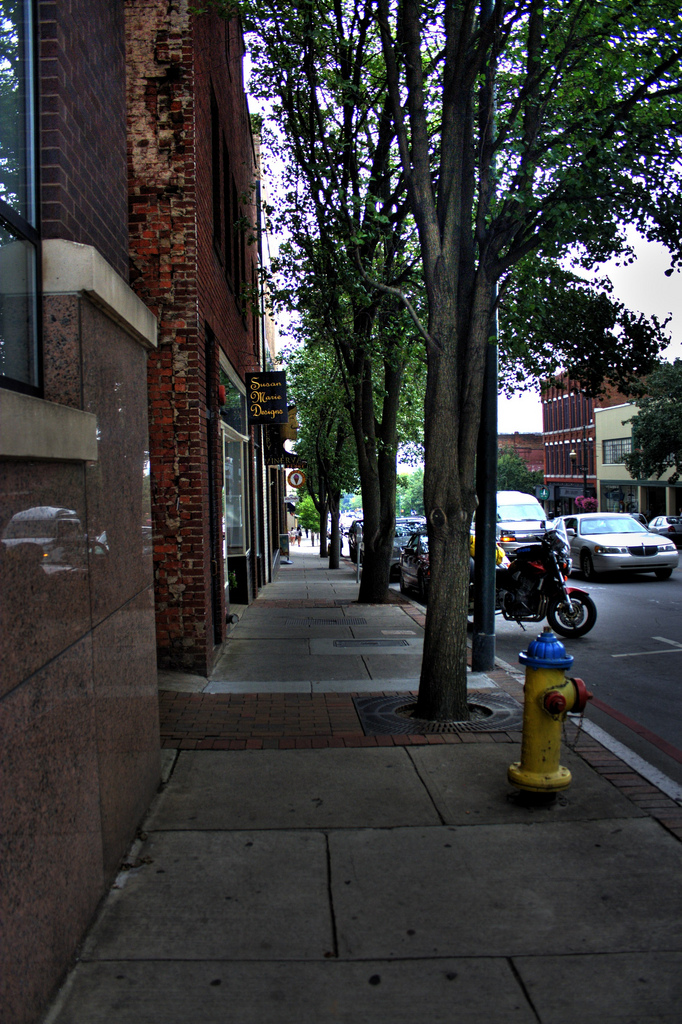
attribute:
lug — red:
[544, 692, 565, 719]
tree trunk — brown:
[420, 337, 468, 717]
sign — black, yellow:
[244, 368, 290, 427]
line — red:
[588, 696, 677, 774]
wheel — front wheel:
[547, 588, 594, 640]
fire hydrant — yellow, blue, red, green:
[507, 628, 590, 809]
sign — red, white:
[288, 472, 302, 486]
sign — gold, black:
[246, 371, 287, 420]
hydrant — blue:
[504, 626, 593, 807]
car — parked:
[650, 515, 681, 541]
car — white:
[553, 513, 677, 580]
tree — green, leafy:
[241, 0, 681, 723]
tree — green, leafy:
[253, 2, 402, 605]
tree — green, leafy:
[283, 273, 428, 568]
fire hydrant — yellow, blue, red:
[509, 622, 584, 809]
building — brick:
[125, 13, 251, 678]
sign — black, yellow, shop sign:
[241, 370, 286, 422]